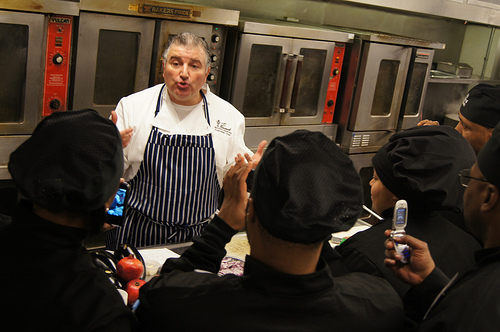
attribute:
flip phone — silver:
[390, 199, 412, 264]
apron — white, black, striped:
[118, 87, 245, 234]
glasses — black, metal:
[443, 167, 495, 192]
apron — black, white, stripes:
[75, 68, 279, 237]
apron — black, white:
[114, 82, 224, 247]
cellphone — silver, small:
[388, 197, 413, 264]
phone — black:
[113, 186, 126, 216]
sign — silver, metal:
[121, 0, 206, 21]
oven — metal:
[233, 15, 354, 137]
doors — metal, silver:
[230, 30, 340, 124]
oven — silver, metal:
[222, 17, 344, 147]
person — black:
[452, 84, 499, 141]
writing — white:
[458, 90, 474, 108]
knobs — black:
[325, 48, 339, 124]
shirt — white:
[114, 82, 244, 192]